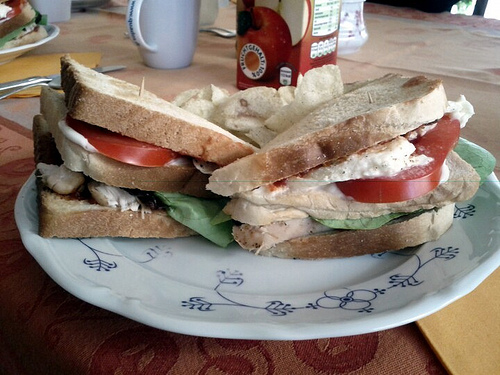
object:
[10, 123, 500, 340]
plate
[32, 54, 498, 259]
food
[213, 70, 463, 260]
sandwich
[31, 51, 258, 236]
sandwich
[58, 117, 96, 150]
mayonnaise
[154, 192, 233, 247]
lettuce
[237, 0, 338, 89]
juice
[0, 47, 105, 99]
napkin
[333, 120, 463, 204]
tomato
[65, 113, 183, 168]
tomato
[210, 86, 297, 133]
chips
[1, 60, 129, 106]
knife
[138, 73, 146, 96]
toothpick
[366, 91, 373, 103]
toothpick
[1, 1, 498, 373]
table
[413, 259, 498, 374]
mat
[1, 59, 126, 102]
fork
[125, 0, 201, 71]
coffee cup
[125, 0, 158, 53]
handle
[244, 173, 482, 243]
chicken